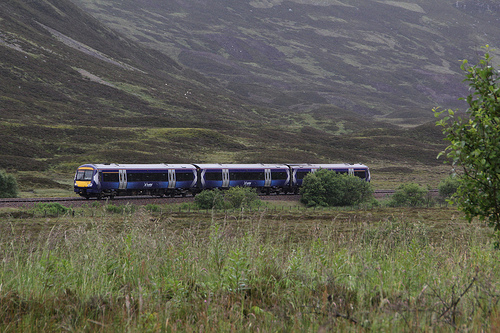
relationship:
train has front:
[73, 163, 371, 199] [71, 165, 99, 199]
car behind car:
[195, 163, 289, 197] [289, 159, 372, 194]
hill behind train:
[2, 1, 496, 184] [73, 163, 371, 199]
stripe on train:
[100, 178, 304, 191] [73, 163, 371, 199]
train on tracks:
[73, 163, 371, 199] [0, 190, 397, 204]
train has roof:
[73, 163, 371, 199] [82, 160, 367, 171]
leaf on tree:
[447, 106, 463, 119] [428, 42, 497, 237]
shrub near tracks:
[299, 169, 375, 211] [0, 190, 397, 204]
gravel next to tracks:
[0, 191, 400, 211] [0, 190, 397, 204]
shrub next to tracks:
[299, 169, 375, 211] [0, 190, 397, 204]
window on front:
[73, 170, 96, 183] [71, 165, 99, 199]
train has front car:
[73, 163, 371, 199] [72, 161, 197, 198]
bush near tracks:
[388, 182, 432, 208] [0, 190, 397, 204]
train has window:
[73, 163, 371, 199] [101, 168, 118, 183]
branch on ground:
[428, 275, 480, 330] [5, 195, 499, 332]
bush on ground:
[388, 182, 432, 208] [5, 195, 499, 332]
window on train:
[101, 168, 118, 183] [73, 163, 371, 199]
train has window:
[73, 163, 371, 199] [73, 170, 96, 183]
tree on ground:
[428, 42, 497, 237] [5, 195, 499, 332]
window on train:
[73, 170, 96, 183] [73, 163, 371, 199]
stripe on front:
[77, 166, 95, 172] [71, 165, 99, 199]